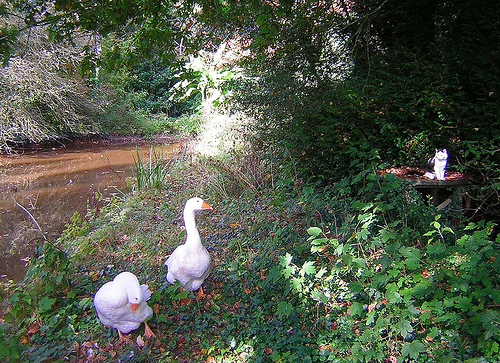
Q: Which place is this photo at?
A: It is at the garden.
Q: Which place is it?
A: It is a garden.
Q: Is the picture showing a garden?
A: Yes, it is showing a garden.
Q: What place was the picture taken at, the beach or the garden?
A: It was taken at the garden.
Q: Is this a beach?
A: No, it is a garden.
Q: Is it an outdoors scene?
A: Yes, it is outdoors.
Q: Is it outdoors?
A: Yes, it is outdoors.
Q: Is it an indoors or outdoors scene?
A: It is outdoors.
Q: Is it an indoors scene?
A: No, it is outdoors.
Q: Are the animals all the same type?
A: No, there are both geese and cats.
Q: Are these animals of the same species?
A: No, there are both geese and cats.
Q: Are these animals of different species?
A: Yes, they are geese and cats.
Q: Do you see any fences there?
A: No, there are no fences.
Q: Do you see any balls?
A: No, there are no balls.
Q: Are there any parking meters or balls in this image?
A: No, there are no balls or parking meters.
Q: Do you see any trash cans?
A: No, there are no trash cans.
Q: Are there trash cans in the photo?
A: No, there are no trash cans.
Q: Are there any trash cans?
A: No, there are no trash cans.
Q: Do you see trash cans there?
A: No, there are no trash cans.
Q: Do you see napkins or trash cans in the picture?
A: No, there are no trash cans or napkins.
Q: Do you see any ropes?
A: No, there are no ropes.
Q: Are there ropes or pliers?
A: No, there are no ropes or pliers.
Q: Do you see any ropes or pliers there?
A: No, there are no ropes or pliers.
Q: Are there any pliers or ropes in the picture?
A: No, there are no ropes or pliers.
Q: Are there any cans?
A: No, there are no cans.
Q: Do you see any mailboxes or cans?
A: No, there are no cans or mailboxes.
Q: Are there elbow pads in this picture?
A: No, there are no elbow pads.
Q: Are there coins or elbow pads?
A: No, there are no elbow pads or coins.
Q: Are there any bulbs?
A: No, there are no bulbs.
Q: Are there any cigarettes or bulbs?
A: No, there are no bulbs or cigarettes.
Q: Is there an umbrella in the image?
A: No, there are no umbrellas.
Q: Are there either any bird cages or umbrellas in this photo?
A: No, there are no umbrellas or bird cages.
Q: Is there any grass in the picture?
A: Yes, there is grass.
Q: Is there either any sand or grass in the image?
A: Yes, there is grass.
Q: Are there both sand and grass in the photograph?
A: No, there is grass but no sand.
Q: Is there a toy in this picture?
A: No, there are no toys.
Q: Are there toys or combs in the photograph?
A: No, there are no toys or combs.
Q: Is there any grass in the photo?
A: Yes, there is grass.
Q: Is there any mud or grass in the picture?
A: Yes, there is grass.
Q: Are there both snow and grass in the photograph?
A: No, there is grass but no snow.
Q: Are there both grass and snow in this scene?
A: No, there is grass but no snow.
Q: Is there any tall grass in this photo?
A: Yes, there is tall grass.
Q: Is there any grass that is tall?
A: Yes, there is grass that is tall.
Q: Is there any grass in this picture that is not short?
A: Yes, there is tall grass.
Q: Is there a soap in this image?
A: No, there are no soaps.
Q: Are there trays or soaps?
A: No, there are no soaps or trays.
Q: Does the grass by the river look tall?
A: Yes, the grass is tall.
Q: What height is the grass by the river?
A: The grass is tall.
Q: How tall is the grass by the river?
A: The grass is tall.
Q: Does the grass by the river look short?
A: No, the grass is tall.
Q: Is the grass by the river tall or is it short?
A: The grass is tall.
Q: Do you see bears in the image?
A: No, there are no bears.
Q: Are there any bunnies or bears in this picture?
A: No, there are no bears or bunnies.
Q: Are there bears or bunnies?
A: No, there are no bears or bunnies.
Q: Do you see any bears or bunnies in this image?
A: No, there are no bears or bunnies.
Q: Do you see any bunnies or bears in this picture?
A: No, there are no bears or bunnies.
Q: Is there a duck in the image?
A: Yes, there are ducks.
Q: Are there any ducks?
A: Yes, there are ducks.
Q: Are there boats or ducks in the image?
A: Yes, there are ducks.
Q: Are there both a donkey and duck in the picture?
A: No, there are ducks but no donkeys.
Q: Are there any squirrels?
A: No, there are no squirrels.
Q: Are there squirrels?
A: No, there are no squirrels.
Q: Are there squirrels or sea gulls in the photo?
A: No, there are no squirrels or sea gulls.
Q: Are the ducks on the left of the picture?
A: Yes, the ducks are on the left of the image.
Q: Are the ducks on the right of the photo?
A: No, the ducks are on the left of the image.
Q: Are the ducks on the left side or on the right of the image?
A: The ducks are on the left of the image.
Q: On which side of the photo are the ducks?
A: The ducks are on the left of the image.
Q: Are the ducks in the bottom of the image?
A: Yes, the ducks are in the bottom of the image.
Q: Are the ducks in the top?
A: No, the ducks are in the bottom of the image.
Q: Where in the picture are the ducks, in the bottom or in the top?
A: The ducks are in the bottom of the image.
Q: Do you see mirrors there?
A: No, there are no mirrors.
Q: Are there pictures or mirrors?
A: No, there are no mirrors or pictures.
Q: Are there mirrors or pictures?
A: No, there are no mirrors or pictures.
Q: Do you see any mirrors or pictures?
A: No, there are no mirrors or pictures.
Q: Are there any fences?
A: No, there are no fences.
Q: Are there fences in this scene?
A: No, there are no fences.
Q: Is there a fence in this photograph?
A: No, there are no fences.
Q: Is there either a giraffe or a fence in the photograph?
A: No, there are no fences or giraffes.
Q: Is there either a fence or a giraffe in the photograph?
A: No, there are no fences or giraffes.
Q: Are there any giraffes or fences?
A: No, there are no fences or giraffes.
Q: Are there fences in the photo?
A: No, there are no fences.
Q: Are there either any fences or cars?
A: No, there are no fences or cars.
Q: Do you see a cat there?
A: Yes, there is a cat.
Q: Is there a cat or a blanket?
A: Yes, there is a cat.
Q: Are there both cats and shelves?
A: No, there is a cat but no shelves.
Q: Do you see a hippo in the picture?
A: No, there are no hippoes.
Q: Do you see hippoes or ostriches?
A: No, there are no hippoes or ostriches.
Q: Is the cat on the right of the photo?
A: Yes, the cat is on the right of the image.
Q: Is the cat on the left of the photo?
A: No, the cat is on the right of the image.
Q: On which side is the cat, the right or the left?
A: The cat is on the right of the image.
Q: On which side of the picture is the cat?
A: The cat is on the right of the image.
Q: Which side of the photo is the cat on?
A: The cat is on the right of the image.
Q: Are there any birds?
A: Yes, there is a bird.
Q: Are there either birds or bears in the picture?
A: Yes, there is a bird.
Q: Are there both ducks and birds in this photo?
A: Yes, there are both a bird and a duck.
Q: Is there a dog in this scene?
A: No, there are no dogs.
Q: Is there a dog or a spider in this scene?
A: No, there are no dogs or spiders.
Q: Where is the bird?
A: The bird is in the grass.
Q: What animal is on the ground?
A: The animal is a bird.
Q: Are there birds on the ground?
A: Yes, there is a bird on the ground.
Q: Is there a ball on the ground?
A: No, there is a bird on the ground.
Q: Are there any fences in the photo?
A: No, there are no fences.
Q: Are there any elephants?
A: No, there are no elephants.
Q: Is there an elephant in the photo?
A: No, there are no elephants.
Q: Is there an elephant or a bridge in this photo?
A: No, there are no elephants or bridges.